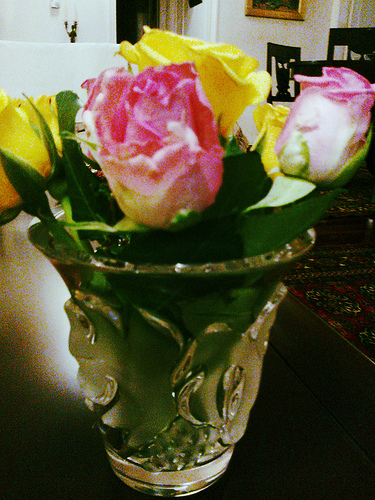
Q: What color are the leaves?
A: Green.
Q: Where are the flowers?
A: In a vase.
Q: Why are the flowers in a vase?
A: To stay fresh.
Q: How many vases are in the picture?
A: One.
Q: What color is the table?
A: Black.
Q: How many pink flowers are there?
A: Two.